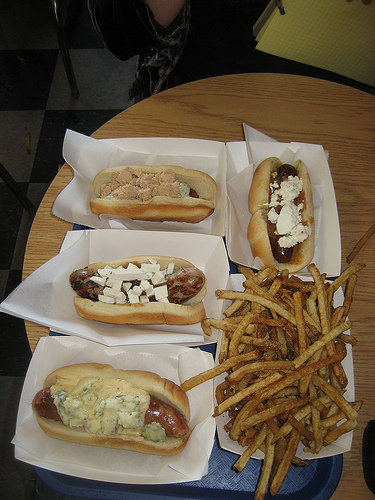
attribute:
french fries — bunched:
[238, 274, 336, 359]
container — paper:
[199, 244, 261, 343]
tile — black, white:
[15, 44, 84, 140]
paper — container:
[5, 212, 170, 276]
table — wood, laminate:
[31, 70, 367, 476]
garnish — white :
[287, 186, 292, 197]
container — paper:
[11, 331, 212, 488]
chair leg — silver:
[47, 4, 87, 106]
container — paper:
[227, 136, 345, 275]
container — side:
[222, 272, 359, 460]